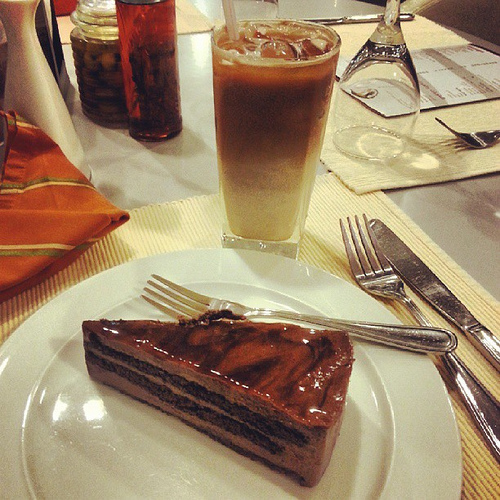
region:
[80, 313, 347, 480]
the glazed chocolate cake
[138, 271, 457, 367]
the fork on the table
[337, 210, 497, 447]
the fork on the table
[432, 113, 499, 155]
the fork on the table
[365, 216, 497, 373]
the silver knife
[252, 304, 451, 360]
the fork on the table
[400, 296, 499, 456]
the fork on the table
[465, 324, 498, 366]
the fork on the table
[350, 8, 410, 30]
the fork on the table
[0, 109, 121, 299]
the orange napkin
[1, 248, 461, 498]
a large white plate on the table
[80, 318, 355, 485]
a piece of chocolate pie on white plate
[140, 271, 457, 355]
a silver fork on the table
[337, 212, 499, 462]
a silver fork on the table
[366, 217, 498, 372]
a silver knife on the table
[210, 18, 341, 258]
a large drink on the table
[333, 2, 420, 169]
a wine glass on the table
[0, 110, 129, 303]
an orange napkin on the table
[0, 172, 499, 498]
a yellow place mat on the atble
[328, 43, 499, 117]
a menu on the table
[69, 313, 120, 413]
cake on a plate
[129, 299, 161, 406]
cake on a plate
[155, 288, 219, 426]
cake on a plate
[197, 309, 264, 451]
cake on a plate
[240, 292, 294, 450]
cake on a plate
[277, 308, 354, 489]
cake on a plate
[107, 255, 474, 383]
fork on a plate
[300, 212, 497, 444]
fork on a table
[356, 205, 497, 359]
knife on a table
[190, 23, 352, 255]
glass on a table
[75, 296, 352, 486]
chocolate cake on a white plate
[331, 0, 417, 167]
upside down wine glass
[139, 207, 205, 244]
yellow striped placemat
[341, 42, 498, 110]
restaurant menu on a placemat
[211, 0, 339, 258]
iced beverage with a straw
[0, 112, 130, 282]
cloth napkin with stripes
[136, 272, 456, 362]
fork on a white plate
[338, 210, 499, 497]
fork and knife next to a round white plate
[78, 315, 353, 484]
layered chocolate cake in the shape of a triangle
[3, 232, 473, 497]
piece of a cake on a plate at a restaurant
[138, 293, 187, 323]
the silver prong of a fork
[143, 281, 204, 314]
the silver prong of a fork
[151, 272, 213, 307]
the silver prong of a fork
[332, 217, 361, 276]
the silver prong of a fork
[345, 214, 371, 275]
the silver prong of a fork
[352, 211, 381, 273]
the silver prong of a fork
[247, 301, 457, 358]
the silver handle of a fork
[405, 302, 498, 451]
the silver handle of a fork